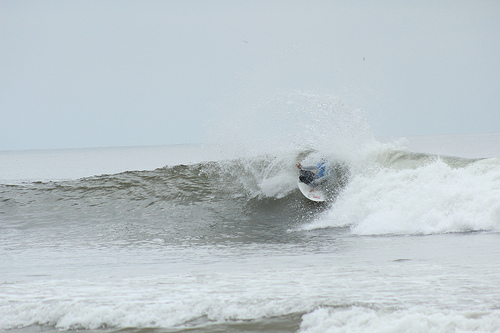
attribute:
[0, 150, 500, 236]
waves — white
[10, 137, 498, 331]
water — gray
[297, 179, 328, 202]
surfboard — white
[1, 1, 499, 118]
sky — hazy